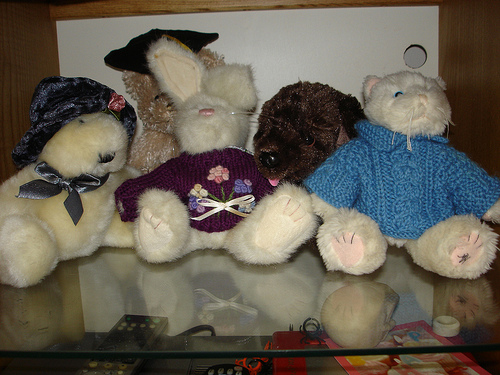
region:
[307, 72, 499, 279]
white plush stuffed cat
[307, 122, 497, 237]
blue cable knit sweater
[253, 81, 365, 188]
brown plush stuffed dog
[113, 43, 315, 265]
white plush stuffed rabbit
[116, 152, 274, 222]
purple cable knit sweater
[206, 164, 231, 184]
pink flower on sweater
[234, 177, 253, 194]
purple flower on sweater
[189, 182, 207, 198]
white flower on sweater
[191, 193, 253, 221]
white bow on sweater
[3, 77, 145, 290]
white plush stuffed bear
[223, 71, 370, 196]
face of the toy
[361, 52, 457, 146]
face of the doll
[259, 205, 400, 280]
legs of the doll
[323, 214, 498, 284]
legs of the toy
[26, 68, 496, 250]
a group of toys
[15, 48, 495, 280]
a group of dolls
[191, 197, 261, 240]
design on the shirt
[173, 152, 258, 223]
design on the doll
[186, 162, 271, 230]
design on the toy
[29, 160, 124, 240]
a tie to head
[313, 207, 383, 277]
foot of a stuffed cat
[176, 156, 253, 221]
flowers knitted on a sweater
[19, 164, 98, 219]
siver bow on a bear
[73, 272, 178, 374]
remote control under glass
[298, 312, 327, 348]
spider ring made of plastic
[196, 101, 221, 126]
pink nose on a bunny toy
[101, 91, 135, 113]
pink rose on a hat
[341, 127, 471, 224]
blue sweater on a stuffed cat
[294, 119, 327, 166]
brown eye on a teddy bear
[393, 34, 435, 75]
circle shaped hole in the white board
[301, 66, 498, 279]
White stuffed cat toy.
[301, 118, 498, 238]
Blue sweater on stuffed animal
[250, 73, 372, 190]
Stuffed toy brown dog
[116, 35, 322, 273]
White stuffed toy rabbit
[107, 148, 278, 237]
Purple vest with flower on a stuffed animal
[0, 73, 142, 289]
White teddy bear with black eyes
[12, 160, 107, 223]
Blue bow on the bears neck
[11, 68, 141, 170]
Blue hat with a pink flower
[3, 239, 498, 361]
Glass shelf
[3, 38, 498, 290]
A group of stuffed animals sitting on a shelf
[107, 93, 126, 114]
a pink rosebud on a hat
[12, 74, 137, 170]
a grey hat on a stuffed bear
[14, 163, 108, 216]
a grey ribbon on a bear's neck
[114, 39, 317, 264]
a bunny in a purple sweater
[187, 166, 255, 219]
a flower bouquet on a purple sweater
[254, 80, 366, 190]
a dog's head peeking out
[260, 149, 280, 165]
the black plastic nose of a dog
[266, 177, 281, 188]
the pink tongue of a stuffed dog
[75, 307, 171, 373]
a grey remote control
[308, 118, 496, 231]
a blue sweater on a stuffed cat